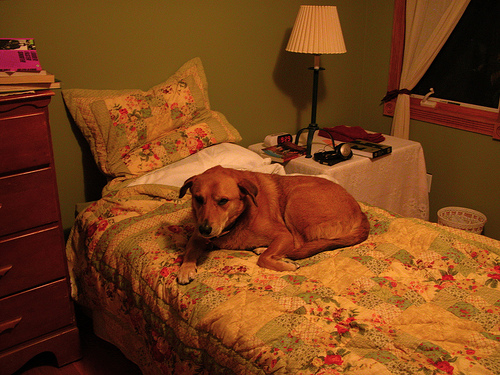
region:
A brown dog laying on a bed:
[174, 163, 371, 288]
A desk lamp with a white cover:
[282, 2, 348, 161]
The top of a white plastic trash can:
[435, 202, 491, 234]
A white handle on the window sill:
[418, 87, 440, 109]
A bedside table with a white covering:
[243, 118, 433, 222]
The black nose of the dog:
[197, 222, 214, 238]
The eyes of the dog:
[188, 191, 232, 209]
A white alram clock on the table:
[262, 130, 296, 148]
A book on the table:
[260, 142, 305, 164]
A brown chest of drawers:
[4, 88, 84, 373]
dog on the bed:
[129, 138, 378, 284]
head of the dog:
[163, 167, 259, 251]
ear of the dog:
[225, 172, 264, 214]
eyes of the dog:
[186, 183, 236, 217]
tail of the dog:
[286, 198, 387, 272]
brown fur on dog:
[248, 170, 328, 226]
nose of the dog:
[183, 209, 225, 249]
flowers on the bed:
[271, 268, 425, 373]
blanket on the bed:
[232, 234, 445, 374]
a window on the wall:
[396, 6, 496, 116]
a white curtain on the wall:
[399, 20, 439, 132]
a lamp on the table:
[285, 18, 347, 138]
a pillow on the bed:
[66, 68, 229, 163]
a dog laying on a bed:
[145, 160, 407, 357]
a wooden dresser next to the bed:
[2, 101, 73, 343]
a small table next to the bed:
[277, 118, 419, 201]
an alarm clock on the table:
[261, 128, 296, 143]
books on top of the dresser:
[8, 41, 54, 106]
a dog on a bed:
[146, 147, 391, 326]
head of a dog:
[165, 163, 272, 243]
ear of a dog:
[163, 165, 202, 207]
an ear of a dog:
[170, 171, 200, 210]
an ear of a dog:
[234, 170, 272, 201]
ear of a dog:
[234, 174, 269, 196]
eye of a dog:
[185, 185, 202, 207]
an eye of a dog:
[190, 188, 208, 203]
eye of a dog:
[210, 191, 240, 207]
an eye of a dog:
[205, 193, 238, 216]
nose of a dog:
[189, 220, 219, 240]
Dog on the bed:
[167, 159, 379, 292]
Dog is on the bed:
[167, 158, 373, 284]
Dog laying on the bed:
[170, 150, 375, 280]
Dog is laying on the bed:
[172, 155, 372, 285]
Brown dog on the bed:
[165, 155, 375, 285]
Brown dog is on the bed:
[171, 155, 376, 285]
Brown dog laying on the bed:
[168, 160, 373, 285]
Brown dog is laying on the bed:
[168, 160, 375, 288]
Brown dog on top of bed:
[164, 164, 379, 287]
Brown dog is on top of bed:
[165, 162, 380, 290]